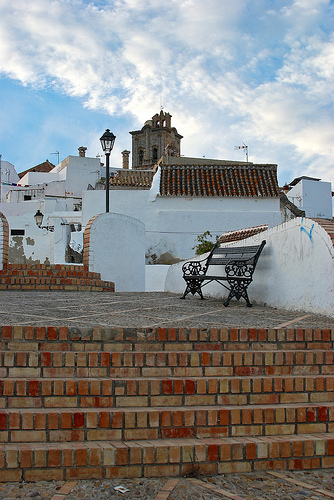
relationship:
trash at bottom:
[83, 471, 156, 499] [21, 455, 332, 499]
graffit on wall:
[286, 209, 333, 275] [229, 212, 327, 318]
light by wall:
[99, 134, 122, 156] [229, 212, 327, 318]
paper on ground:
[83, 471, 156, 499] [26, 474, 204, 499]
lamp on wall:
[94, 130, 156, 209] [229, 212, 327, 318]